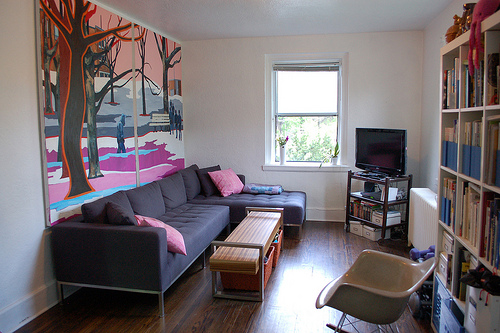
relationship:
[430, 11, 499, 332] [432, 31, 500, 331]
bookcase has books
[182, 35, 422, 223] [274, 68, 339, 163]
wall has a window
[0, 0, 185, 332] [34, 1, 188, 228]
wall has a painting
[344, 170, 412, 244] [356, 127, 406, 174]
shelfing has a tv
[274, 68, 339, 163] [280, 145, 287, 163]
window has a vase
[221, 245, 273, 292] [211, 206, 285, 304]
boxes are underneath table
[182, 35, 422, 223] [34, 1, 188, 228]
wall has a painting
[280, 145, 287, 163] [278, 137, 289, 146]
vase has flowers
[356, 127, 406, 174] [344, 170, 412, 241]
tv on a stand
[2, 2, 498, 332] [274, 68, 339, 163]
room has a window